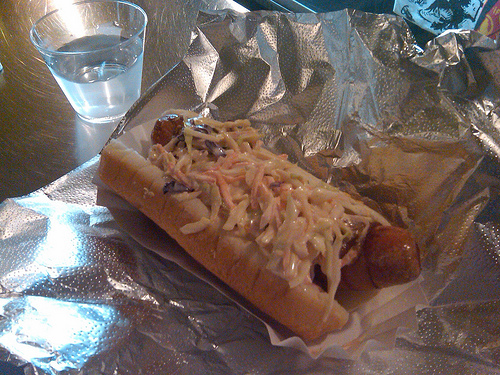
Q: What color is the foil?
A: Silver.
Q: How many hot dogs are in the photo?
A: One.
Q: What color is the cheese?
A: Yellow.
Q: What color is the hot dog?
A: Red.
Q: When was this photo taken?
A: During the day.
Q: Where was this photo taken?
A: At a restaurant.